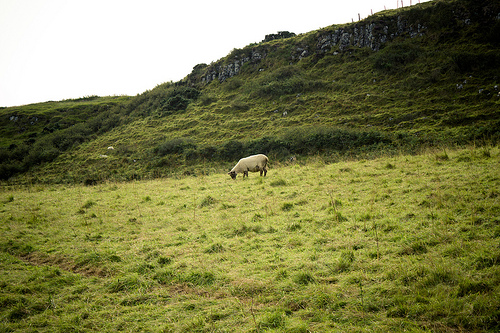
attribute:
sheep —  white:
[229, 151, 268, 180]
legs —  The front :
[231, 165, 304, 192]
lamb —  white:
[228, 151, 271, 181]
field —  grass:
[16, 188, 498, 299]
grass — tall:
[161, 190, 461, 331]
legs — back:
[258, 165, 273, 182]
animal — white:
[165, 140, 316, 232]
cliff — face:
[206, 18, 398, 48]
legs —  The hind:
[254, 168, 271, 178]